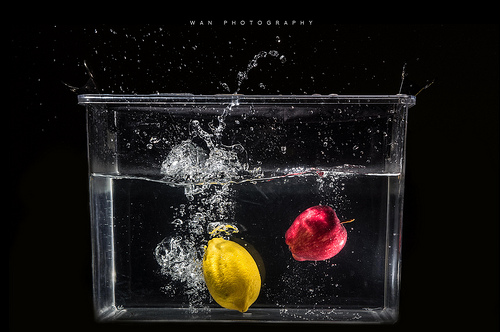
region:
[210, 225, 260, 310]
a whole lemon in water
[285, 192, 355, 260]
a red apple in water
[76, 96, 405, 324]
a clear container of water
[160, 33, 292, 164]
a splash of water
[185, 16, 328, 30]
the name of the photographer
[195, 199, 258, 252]
bubbles in the water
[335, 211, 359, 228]
a stem of an apple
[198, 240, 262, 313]
an unpeeled lemon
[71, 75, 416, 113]
the lip of a clear container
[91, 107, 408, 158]
spots of water on the side of the container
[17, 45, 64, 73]
a black backgroung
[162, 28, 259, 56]
a black backgroung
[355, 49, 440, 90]
a black backgroung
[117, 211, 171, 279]
the water is clear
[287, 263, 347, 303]
the water is clear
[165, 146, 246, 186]
this is splashed water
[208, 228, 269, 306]
that is a yellow fruit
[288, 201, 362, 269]
that is a red fruit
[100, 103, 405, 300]
a glass container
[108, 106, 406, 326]
the container is not full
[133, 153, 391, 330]
an apple and lemon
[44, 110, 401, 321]
a bowl of water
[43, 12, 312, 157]
a black background is professional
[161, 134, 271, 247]
water splashes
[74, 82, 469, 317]
a clear bowl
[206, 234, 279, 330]
the lemon is yellow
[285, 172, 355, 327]
the apple is red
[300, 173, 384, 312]
the apple has a stem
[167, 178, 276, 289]
bubbles in the water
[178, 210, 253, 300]
the lemon touches the bottom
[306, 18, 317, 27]
white letter on picture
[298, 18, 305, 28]
white letter on picture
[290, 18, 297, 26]
white letter on picture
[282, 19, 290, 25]
white letter on picture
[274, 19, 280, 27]
white letter on picture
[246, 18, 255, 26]
white letter on picture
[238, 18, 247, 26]
white letter on picture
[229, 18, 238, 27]
white letter on picture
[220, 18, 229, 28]
white letter on picture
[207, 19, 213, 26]
white letter on picture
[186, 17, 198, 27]
white letter on picture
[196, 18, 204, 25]
white letter on picture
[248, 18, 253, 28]
white letter on picture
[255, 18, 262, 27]
white letter on picture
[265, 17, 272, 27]
white letter on picture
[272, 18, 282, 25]
white letter on picture